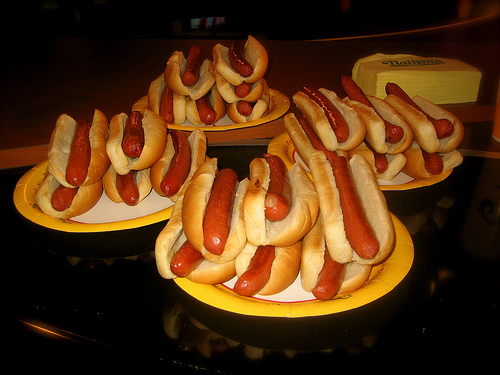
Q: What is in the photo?
A: Hot dogs.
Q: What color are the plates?
A: Yellow.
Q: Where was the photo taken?
A: Near some hot dogs.